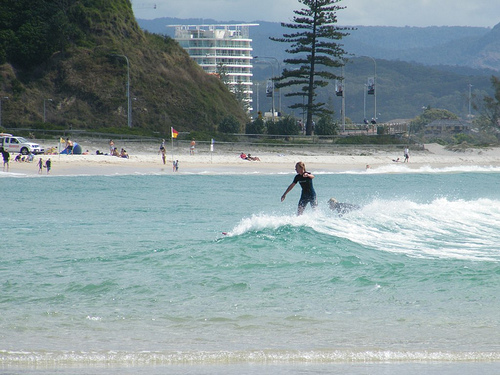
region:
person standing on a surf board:
[275, 151, 324, 222]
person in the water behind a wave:
[325, 193, 362, 220]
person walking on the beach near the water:
[155, 138, 170, 167]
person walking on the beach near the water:
[400, 141, 413, 166]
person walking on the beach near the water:
[43, 155, 53, 172]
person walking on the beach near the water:
[35, 155, 45, 173]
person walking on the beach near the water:
[0, 146, 13, 169]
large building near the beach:
[163, 20, 264, 125]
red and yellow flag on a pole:
[165, 123, 178, 154]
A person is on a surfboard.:
[218, 157, 340, 242]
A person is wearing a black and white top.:
[287, 169, 316, 194]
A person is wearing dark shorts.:
[296, 189, 320, 211]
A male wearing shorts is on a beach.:
[60, 135, 74, 153]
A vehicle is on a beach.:
[0, 129, 46, 159]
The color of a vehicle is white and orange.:
[0, 130, 46, 157]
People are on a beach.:
[0, 133, 413, 175]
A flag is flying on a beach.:
[165, 120, 179, 154]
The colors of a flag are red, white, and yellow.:
[166, 123, 181, 153]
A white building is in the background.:
[160, 18, 257, 129]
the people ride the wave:
[274, 154, 361, 219]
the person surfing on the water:
[277, 156, 316, 220]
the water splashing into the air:
[228, 194, 498, 269]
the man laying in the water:
[323, 195, 373, 224]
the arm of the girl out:
[275, 173, 299, 207]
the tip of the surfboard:
[219, 227, 233, 239]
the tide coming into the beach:
[18, 339, 499, 374]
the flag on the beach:
[169, 125, 179, 162]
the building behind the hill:
[168, 22, 256, 70]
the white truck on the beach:
[0, 136, 41, 154]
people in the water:
[285, 143, 407, 243]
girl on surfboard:
[279, 135, 326, 226]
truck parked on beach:
[2, 124, 36, 158]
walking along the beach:
[26, 148, 67, 182]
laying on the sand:
[226, 147, 267, 164]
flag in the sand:
[160, 123, 181, 157]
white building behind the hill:
[150, 9, 283, 137]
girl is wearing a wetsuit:
[284, 156, 332, 221]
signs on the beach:
[201, 135, 219, 172]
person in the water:
[354, 160, 379, 180]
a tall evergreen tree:
[281, 0, 331, 138]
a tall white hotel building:
[155, 13, 275, 119]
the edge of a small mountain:
[20, 7, 227, 146]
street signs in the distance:
[337, 83, 391, 133]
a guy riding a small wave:
[271, 172, 357, 247]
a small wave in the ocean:
[353, 187, 483, 283]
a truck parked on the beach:
[2, 132, 47, 169]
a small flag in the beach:
[165, 128, 182, 158]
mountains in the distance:
[395, 25, 461, 110]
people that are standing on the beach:
[34, 151, 68, 177]